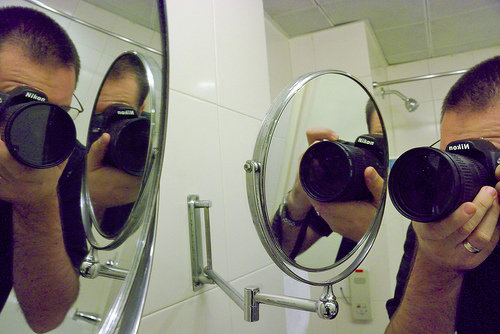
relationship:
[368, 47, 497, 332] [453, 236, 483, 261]
man wearing ring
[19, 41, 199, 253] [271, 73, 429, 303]
man in mirror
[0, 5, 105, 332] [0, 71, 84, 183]
man with camera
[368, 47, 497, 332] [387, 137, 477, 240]
man with camera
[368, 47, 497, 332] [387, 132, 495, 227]
man with camera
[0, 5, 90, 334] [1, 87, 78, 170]
man with camera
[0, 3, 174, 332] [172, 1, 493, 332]
mirror on wall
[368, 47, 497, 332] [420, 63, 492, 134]
man with hair